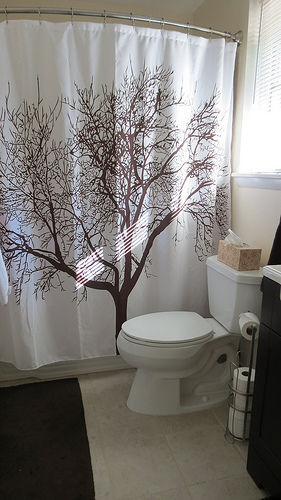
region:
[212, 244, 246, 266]
Kleenex box on back of toilet.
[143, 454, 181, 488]
White tile on floor in bathroom.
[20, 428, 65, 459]
Bath mat on floor in bathroom.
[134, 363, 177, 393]
White toilet in bathroom.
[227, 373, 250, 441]
Extra toilet paper in holder.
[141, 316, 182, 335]
Lid on toilet is white.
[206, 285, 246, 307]
Tank on toilet is white.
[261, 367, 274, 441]
Black cupboard in bathroom.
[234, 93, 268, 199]
Window above toilet in bathroom.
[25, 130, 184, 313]
Brown tree on white shower curtain.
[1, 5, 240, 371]
bathroom has shower curtain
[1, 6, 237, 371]
shower curtain has a brown tree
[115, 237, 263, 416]
toilet is next to shower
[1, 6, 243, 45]
shower curtain rod is curved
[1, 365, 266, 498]
floor tiles are beige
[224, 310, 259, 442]
toilet paper rolls on toilet holder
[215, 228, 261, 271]
tissue box on top of toilet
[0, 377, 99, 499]
brown rug on floor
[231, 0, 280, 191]
window over the toilet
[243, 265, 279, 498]
brown vanity next to toilet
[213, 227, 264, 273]
tissue box on the back of toliet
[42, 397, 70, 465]
brown rug on the floor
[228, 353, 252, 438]
toliet paper holder next to the sink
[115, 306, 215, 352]
toliet seat cover on the toliet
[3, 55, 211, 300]
brown tree on the shower curtain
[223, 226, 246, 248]
tissues in the tissue box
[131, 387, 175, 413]
base of the toliet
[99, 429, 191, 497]
square on the floor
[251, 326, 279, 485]
cupboard on the sink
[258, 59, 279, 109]
white blinds on the window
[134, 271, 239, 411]
a white toilet bowl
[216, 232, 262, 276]
a box of tissues on a toilet tank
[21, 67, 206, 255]
a shower curtain with a tree design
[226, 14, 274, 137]
a window covered by a mini blind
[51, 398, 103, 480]
a rug on the floor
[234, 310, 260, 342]
a roll of toilet paper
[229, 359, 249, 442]
a stack of toilet paper rolls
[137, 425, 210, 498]
a tile floor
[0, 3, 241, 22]
a silver shower curtain rod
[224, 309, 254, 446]
a toilet paper holder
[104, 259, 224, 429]
White toilet in background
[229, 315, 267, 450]
Toilet paper in bathroom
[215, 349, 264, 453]
Toilet paper in rack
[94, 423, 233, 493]
White tile in bathroom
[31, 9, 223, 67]
White shower curtain hanging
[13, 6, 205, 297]
Shower curtain with tree pattern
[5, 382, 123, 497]
Brown bath mat in bathroom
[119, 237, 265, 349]
Tan tissue box on top of toilet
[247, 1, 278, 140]
Window with venetian blinds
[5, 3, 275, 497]
Bathroom with white and brown color scheme